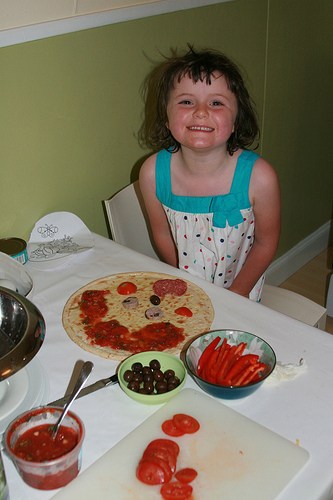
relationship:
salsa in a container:
[14, 423, 83, 490] [3, 406, 86, 491]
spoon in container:
[51, 361, 93, 440] [3, 406, 86, 491]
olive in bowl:
[150, 359, 160, 371] [116, 351, 186, 405]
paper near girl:
[25, 209, 95, 262] [138, 41, 280, 303]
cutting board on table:
[47, 389, 308, 500] [0, 230, 332, 499]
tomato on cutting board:
[172, 413, 199, 434] [47, 389, 308, 500]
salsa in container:
[14, 423, 83, 490] [3, 406, 86, 491]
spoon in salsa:
[51, 361, 93, 440] [14, 423, 82, 488]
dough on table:
[64, 271, 213, 361] [0, 230, 332, 499]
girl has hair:
[138, 41, 280, 303] [148, 41, 262, 156]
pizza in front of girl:
[62, 272, 213, 360] [138, 41, 280, 303]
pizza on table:
[62, 272, 213, 360] [0, 230, 332, 499]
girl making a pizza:
[138, 41, 280, 303] [62, 272, 213, 360]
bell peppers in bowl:
[195, 335, 266, 388] [184, 329, 276, 399]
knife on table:
[45, 373, 119, 404] [0, 230, 332, 499]